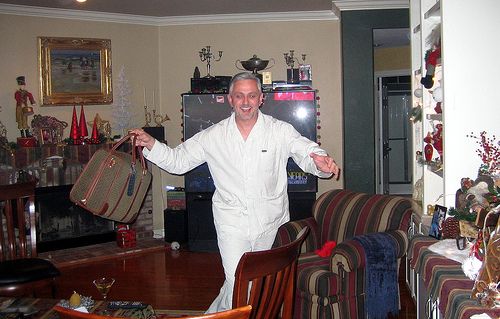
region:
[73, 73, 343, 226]
man holding a suitcase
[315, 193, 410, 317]
striped armchair with a blue blanket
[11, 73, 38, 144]
Christmas soldier decoration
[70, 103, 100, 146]
three red Christmas trees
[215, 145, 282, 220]
man's white uniform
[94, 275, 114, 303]
martini glass on a table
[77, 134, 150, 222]
brown and green suitcase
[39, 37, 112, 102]
artwork with a gold frame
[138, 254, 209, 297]
brown wood floor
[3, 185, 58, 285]
brown chair with a black padded seat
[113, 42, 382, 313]
a man in a bathrobe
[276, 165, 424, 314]
a striped chair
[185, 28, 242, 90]
a simple metal candle holder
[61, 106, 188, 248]
a green and brown piece of luggage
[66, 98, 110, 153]
a few red christmas decorations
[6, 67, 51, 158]
a tall nutcracker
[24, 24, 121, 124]
an ornate gold frame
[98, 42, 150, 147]
a fake white Christmas tree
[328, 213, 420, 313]
a dark blue chenille throw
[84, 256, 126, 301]
a clear martini glass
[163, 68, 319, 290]
smiling man with grey hair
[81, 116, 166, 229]
suitcase in mans hand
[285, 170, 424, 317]
red and green striped chair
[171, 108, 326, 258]
white bathrobe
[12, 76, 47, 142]
little drummer boy figurine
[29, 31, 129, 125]
picture with gold frame on wall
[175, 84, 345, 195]
big screen television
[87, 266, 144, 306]
martini glass on table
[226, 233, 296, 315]
wooden chair against table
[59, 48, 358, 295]
man swinging a bag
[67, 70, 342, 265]
a man holding a suitcase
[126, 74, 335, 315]
the man is wearing a white robe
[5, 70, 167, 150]
decorations for Christmas are on the mantel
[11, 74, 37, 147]
a nutcracker is standing on the mantel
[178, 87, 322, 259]
big screen tv is in the background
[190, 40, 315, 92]
candlesticks are above the tv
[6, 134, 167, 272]
the room has a brick fireplace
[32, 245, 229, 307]
the living room has a wood floor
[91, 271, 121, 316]
a glass of champagne is on the table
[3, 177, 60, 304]
the room has a wood chair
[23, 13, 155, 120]
"A painting on the wall"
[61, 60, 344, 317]
"Man holding a suitcase"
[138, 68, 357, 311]
"The man is dressed in all white"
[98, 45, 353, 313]
"The man is smiling"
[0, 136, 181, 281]
"A brick fireplace is shown"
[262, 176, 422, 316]
"A striped, fabric chair is seen"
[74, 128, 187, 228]
"The suitcase has brown straps"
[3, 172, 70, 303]
"Brown wood chair with black seat"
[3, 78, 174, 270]
"The fireplace is cluttered on top"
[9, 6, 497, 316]
"The living room is really cluttered"